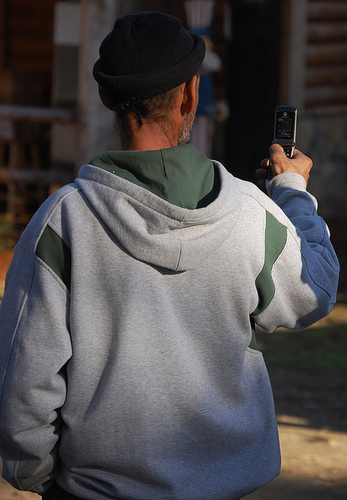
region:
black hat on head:
[87, 13, 207, 94]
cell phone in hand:
[272, 105, 298, 169]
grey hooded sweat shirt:
[9, 148, 340, 498]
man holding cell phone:
[4, 3, 338, 498]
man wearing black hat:
[0, 4, 339, 498]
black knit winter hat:
[94, 8, 204, 97]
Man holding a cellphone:
[260, 99, 296, 168]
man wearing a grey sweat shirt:
[43, 231, 283, 483]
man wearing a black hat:
[77, 8, 204, 101]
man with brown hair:
[91, 85, 173, 132]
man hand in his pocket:
[5, 395, 79, 496]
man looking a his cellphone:
[265, 99, 300, 170]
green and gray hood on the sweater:
[89, 142, 220, 239]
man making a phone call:
[261, 105, 293, 173]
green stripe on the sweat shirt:
[250, 179, 303, 317]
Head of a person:
[83, 5, 226, 177]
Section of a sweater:
[192, 416, 284, 497]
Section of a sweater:
[115, 291, 199, 379]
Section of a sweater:
[205, 292, 275, 415]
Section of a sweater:
[64, 419, 181, 498]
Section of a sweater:
[21, 208, 120, 340]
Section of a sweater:
[158, 189, 258, 349]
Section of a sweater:
[162, 384, 269, 488]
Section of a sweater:
[198, 214, 325, 406]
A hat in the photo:
[93, 17, 192, 91]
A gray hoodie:
[105, 277, 251, 456]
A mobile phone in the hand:
[259, 108, 308, 193]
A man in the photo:
[92, 87, 251, 493]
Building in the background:
[260, 8, 340, 87]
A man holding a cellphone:
[266, 93, 303, 177]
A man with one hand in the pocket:
[1, 256, 249, 492]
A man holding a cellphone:
[255, 82, 328, 243]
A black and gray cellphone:
[267, 104, 304, 169]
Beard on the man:
[168, 118, 193, 152]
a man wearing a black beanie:
[92, 6, 285, 234]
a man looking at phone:
[74, 9, 344, 236]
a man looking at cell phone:
[80, 11, 337, 271]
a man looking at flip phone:
[97, 25, 336, 228]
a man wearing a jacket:
[27, 48, 331, 431]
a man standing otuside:
[68, 43, 292, 379]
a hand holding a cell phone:
[248, 91, 319, 187]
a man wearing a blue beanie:
[66, 4, 225, 151]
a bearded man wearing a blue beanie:
[89, 3, 222, 157]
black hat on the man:
[78, 10, 206, 151]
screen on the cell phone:
[275, 108, 296, 140]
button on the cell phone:
[284, 150, 292, 156]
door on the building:
[205, 3, 293, 177]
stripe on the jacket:
[239, 199, 290, 324]